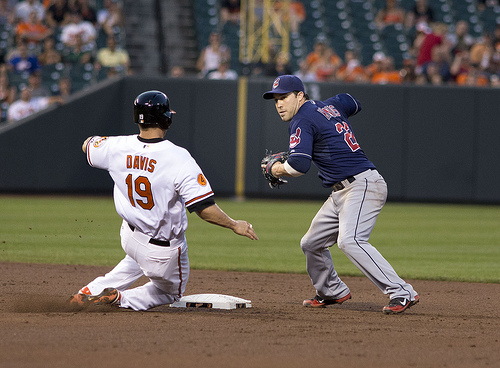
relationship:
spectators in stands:
[8, 4, 490, 94] [4, 2, 494, 144]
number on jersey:
[123, 171, 134, 208] [83, 132, 215, 242]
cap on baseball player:
[266, 74, 308, 97] [257, 73, 421, 316]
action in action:
[71, 67, 436, 319] [66, 73, 421, 316]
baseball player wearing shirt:
[257, 73, 421, 316] [279, 89, 380, 189]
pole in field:
[237, 38, 255, 193] [1, 190, 498, 244]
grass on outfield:
[438, 190, 479, 246] [4, 201, 495, 278]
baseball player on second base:
[62, 89, 258, 314] [13, 255, 279, 355]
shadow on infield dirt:
[95, 280, 250, 322] [14, 243, 471, 365]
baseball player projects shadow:
[66, 87, 257, 337] [95, 280, 250, 322]